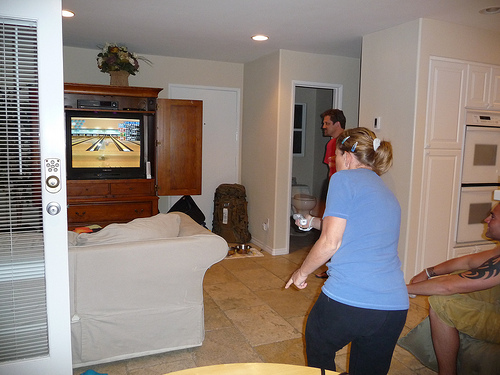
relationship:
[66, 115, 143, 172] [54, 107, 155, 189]
bowling alley on television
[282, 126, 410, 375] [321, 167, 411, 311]
lady wearing blue top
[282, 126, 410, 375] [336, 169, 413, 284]
lady wearing blue top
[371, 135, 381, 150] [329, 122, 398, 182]
band in hair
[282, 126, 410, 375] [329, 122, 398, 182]
lady has hair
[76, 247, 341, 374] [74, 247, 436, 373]
tile on floor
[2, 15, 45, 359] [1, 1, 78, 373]
mini blinds over door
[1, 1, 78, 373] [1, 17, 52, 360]
door has glass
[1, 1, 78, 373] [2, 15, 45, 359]
door has mini blinds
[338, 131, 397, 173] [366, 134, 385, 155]
hair tied with band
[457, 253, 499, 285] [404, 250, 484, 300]
tattoo on arm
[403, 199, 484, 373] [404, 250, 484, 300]
man has arm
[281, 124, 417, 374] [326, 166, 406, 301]
lady with shirt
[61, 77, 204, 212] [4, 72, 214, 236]
television in cabinet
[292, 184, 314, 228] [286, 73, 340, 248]
toilet in bathroom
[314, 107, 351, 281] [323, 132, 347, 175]
man with shirt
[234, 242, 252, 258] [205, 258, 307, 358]
bowl on floor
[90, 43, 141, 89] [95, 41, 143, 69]
flower basket of flowers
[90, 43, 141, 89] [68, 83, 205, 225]
flower basket on top cabinet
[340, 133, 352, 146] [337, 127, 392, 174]
barrett on hair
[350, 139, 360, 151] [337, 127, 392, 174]
barrett on hair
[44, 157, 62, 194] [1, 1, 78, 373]
door lock on door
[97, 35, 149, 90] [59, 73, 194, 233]
flower basket on television stand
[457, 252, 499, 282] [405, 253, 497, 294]
tattoo on arm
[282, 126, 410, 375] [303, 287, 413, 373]
lady wearing pants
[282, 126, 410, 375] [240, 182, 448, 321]
lady wearing shirt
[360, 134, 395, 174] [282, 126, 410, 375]
pony tail on lady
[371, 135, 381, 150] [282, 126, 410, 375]
band on lady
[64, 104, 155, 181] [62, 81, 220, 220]
television in cabinet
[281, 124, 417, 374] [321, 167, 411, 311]
lady wearing blue top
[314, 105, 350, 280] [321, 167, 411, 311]
man wearing blue top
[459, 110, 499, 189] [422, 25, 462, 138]
oven on wall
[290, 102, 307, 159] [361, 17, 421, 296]
window on wall